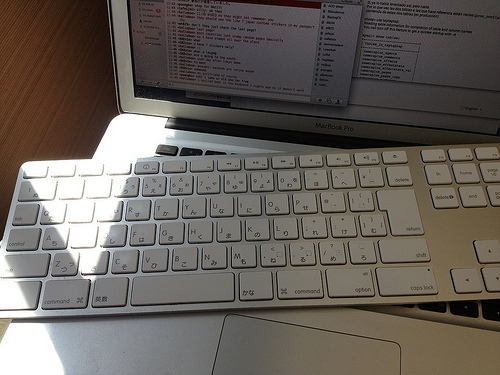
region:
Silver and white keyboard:
[3, 149, 499, 319]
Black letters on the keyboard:
[8, 134, 499, 345]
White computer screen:
[125, 28, 499, 158]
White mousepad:
[201, 303, 428, 373]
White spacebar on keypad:
[127, 273, 248, 307]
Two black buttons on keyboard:
[154, 135, 214, 162]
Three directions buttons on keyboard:
[444, 236, 499, 311]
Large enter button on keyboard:
[371, 188, 432, 243]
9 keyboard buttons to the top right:
[422, 146, 499, 210]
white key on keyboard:
[39, 204, 69, 222]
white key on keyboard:
[69, 199, 94, 222]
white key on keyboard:
[95, 200, 121, 220]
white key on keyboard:
[126, 198, 151, 221]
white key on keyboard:
[155, 198, 179, 221]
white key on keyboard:
[180, 196, 205, 217]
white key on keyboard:
[208, 198, 233, 216]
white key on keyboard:
[236, 194, 262, 215]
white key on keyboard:
[262, 193, 287, 216]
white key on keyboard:
[291, 192, 318, 214]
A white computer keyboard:
[5, 160, 487, 290]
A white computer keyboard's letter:
[228, 243, 252, 267]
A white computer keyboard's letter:
[197, 244, 221, 269]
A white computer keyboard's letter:
[241, 215, 266, 243]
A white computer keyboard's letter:
[185, 214, 215, 251]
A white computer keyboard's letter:
[127, 224, 152, 248]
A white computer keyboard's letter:
[114, 250, 142, 272]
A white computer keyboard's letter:
[142, 241, 173, 273]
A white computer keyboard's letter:
[211, 190, 232, 222]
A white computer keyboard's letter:
[122, 200, 147, 227]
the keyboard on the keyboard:
[15, 150, 497, 302]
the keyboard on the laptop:
[2, 122, 497, 360]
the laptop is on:
[107, 5, 497, 143]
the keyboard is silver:
[15, 149, 498, 331]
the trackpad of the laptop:
[205, 311, 410, 373]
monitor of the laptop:
[97, 0, 494, 131]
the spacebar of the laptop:
[136, 275, 238, 302]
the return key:
[363, 185, 429, 235]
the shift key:
[370, 237, 444, 269]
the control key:
[2, 233, 40, 248]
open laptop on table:
[0, 3, 495, 372]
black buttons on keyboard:
[438, 301, 498, 318]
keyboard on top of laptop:
[0, 145, 497, 321]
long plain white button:
[128, 269, 234, 306]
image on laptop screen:
[131, 3, 497, 110]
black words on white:
[173, 6, 300, 85]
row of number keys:
[30, 169, 300, 203]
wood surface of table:
[0, 8, 113, 205]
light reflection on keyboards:
[31, 112, 166, 265]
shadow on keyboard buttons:
[9, 181, 87, 328]